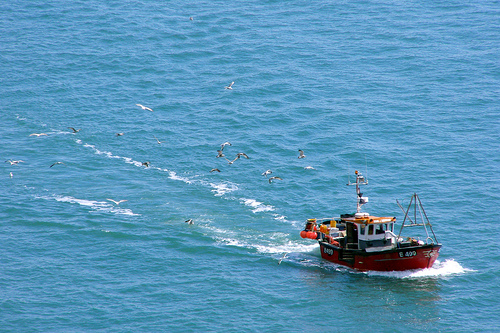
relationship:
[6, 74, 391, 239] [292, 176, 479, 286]
seagulls follow boat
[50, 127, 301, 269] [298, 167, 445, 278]
wake of boat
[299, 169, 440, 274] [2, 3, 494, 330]
boat in water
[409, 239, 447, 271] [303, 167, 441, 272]
bow of boat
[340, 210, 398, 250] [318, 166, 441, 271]
cabin of boat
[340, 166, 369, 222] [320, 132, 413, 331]
pole on top of boat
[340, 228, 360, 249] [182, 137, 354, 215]
window in buoys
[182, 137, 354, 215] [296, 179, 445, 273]
buoys of boat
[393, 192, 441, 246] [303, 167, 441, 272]
tri-pod on front of boat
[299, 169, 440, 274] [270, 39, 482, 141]
boat on water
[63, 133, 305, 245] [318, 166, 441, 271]
trail of boat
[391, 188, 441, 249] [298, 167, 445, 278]
tri-pod on boat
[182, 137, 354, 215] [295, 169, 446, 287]
buoys of boats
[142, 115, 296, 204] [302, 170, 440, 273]
seagulls following fishing boats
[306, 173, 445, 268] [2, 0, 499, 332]
boat moving through ocean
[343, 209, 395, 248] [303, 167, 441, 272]
bridge of boat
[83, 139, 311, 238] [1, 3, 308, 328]
ripples in water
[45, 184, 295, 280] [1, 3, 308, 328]
ripples in water